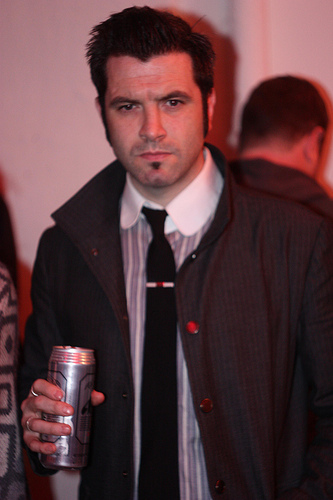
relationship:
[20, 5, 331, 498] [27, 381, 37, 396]
guy has ring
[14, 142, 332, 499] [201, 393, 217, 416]
jacket has button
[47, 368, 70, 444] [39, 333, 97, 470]
wiring on can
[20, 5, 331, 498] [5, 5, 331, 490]
guy face camera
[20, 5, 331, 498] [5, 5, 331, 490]
guy looks camera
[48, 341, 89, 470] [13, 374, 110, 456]
drink on hand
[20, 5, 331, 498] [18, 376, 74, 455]
guy has fingers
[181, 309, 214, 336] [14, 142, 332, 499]
button on jacket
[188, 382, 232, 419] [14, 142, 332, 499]
button on jacket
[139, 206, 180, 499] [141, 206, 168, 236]
tie has knot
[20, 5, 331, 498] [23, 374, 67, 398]
guy has finger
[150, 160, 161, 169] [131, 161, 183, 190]
hair on chin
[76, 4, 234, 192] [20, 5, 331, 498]
head of guy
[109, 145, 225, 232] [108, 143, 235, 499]
white collar on shirt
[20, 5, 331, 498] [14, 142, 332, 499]
guy wearing jacket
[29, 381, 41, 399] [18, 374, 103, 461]
ring on finger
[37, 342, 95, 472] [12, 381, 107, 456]
can in hand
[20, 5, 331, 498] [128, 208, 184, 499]
guy wearing tie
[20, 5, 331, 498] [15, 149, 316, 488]
guy wearing jacket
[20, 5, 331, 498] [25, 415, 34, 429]
guy has ring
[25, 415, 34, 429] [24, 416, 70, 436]
ring on finger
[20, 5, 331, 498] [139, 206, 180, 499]
guy has tie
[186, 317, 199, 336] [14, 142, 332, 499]
button on jacket